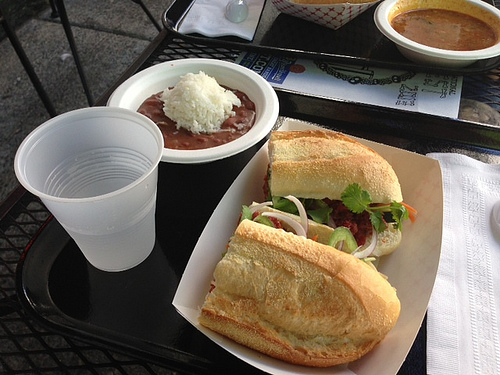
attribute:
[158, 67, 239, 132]
rice — white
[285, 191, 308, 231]
onion slice — sliced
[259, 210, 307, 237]
onion slice — sliced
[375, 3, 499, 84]
dish — WHITE